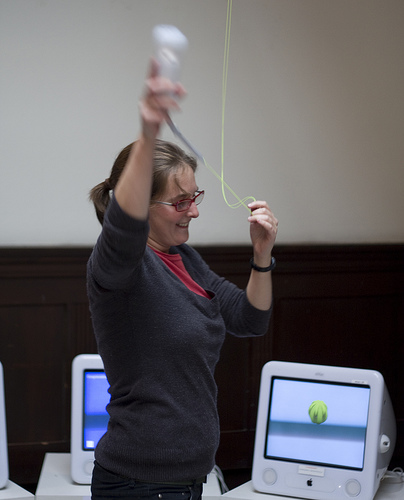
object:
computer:
[244, 357, 404, 499]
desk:
[220, 467, 402, 499]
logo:
[301, 477, 319, 491]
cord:
[210, 462, 234, 498]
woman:
[84, 127, 278, 500]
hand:
[242, 196, 282, 265]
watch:
[251, 252, 278, 281]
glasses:
[165, 190, 210, 211]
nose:
[187, 202, 199, 222]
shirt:
[80, 200, 276, 488]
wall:
[1, 1, 401, 500]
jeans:
[85, 461, 211, 499]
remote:
[146, 20, 189, 105]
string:
[162, 3, 267, 226]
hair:
[90, 139, 196, 229]